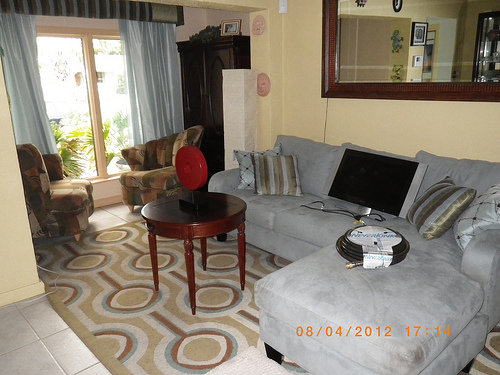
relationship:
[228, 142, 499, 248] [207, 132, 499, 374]
pillows on top of sectional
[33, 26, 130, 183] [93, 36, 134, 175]
frame around window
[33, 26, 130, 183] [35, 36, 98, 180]
frame around window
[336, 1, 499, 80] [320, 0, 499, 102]
mirror inside frame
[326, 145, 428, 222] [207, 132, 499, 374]
television sitting on sectional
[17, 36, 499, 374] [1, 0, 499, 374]
furniture inside of living room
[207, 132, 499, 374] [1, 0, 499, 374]
sectional inside of living room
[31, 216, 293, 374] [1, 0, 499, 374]
area rug inside of living room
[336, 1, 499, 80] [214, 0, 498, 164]
mirror hanging on walls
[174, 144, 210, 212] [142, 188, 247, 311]
statue in middle of table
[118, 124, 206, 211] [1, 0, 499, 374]
chair inside of living room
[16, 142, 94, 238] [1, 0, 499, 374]
chair inside of living room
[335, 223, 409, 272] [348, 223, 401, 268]
cable inside of packaging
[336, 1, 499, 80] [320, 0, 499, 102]
mirror inside of frame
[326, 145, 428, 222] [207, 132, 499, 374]
television on top of sectional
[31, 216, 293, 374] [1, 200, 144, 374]
area rug on top of tile floor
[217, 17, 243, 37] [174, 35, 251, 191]
framed picture on top of cabinet